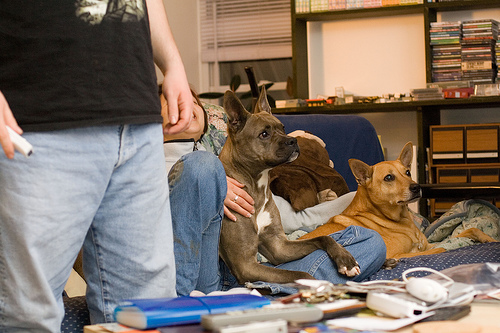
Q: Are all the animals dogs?
A: Yes, all the animals are dogs.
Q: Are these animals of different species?
A: No, all the animals are dogs.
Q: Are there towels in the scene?
A: No, there are no towels.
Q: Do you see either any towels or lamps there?
A: No, there are no towels or lamps.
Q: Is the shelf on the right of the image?
A: Yes, the shelf is on the right of the image.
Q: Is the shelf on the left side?
A: No, the shelf is on the right of the image.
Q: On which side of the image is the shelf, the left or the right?
A: The shelf is on the right of the image.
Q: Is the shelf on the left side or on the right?
A: The shelf is on the right of the image.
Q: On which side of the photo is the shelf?
A: The shelf is on the right of the image.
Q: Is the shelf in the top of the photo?
A: Yes, the shelf is in the top of the image.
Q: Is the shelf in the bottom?
A: No, the shelf is in the top of the image.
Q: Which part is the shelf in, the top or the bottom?
A: The shelf is in the top of the image.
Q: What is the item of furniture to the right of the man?
A: The piece of furniture is a shelf.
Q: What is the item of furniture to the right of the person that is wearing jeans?
A: The piece of furniture is a shelf.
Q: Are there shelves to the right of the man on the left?
A: Yes, there is a shelf to the right of the man.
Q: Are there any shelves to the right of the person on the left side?
A: Yes, there is a shelf to the right of the man.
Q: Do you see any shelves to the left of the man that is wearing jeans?
A: No, the shelf is to the right of the man.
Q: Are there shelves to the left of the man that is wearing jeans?
A: No, the shelf is to the right of the man.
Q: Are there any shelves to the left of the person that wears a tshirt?
A: No, the shelf is to the right of the man.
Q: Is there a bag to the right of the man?
A: No, there is a shelf to the right of the man.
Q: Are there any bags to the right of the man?
A: No, there is a shelf to the right of the man.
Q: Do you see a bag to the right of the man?
A: No, there is a shelf to the right of the man.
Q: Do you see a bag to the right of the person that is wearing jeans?
A: No, there is a shelf to the right of the man.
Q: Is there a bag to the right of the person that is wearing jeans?
A: No, there is a shelf to the right of the man.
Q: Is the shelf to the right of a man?
A: Yes, the shelf is to the right of a man.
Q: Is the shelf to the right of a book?
A: No, the shelf is to the right of a man.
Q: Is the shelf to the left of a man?
A: No, the shelf is to the right of a man.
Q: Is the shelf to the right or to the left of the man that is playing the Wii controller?
A: The shelf is to the right of the man.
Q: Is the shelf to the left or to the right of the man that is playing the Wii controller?
A: The shelf is to the right of the man.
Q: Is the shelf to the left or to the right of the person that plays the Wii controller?
A: The shelf is to the right of the man.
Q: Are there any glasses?
A: No, there are no glasses.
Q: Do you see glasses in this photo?
A: No, there are no glasses.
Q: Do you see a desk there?
A: Yes, there is a desk.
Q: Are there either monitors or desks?
A: Yes, there is a desk.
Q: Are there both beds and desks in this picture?
A: No, there is a desk but no beds.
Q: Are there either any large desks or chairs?
A: Yes, there is a large desk.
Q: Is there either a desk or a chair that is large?
A: Yes, the desk is large.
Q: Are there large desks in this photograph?
A: Yes, there is a large desk.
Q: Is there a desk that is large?
A: Yes, there is a desk that is large.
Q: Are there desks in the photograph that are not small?
A: Yes, there is a large desk.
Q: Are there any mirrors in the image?
A: No, there are no mirrors.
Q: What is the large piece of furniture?
A: The piece of furniture is a desk.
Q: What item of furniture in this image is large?
A: The piece of furniture is a desk.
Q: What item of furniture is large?
A: The piece of furniture is a desk.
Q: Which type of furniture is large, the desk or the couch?
A: The desk is large.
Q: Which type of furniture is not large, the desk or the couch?
A: The couch is not large.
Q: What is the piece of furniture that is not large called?
A: The piece of furniture is a couch.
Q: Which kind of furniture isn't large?
A: The furniture is a couch.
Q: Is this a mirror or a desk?
A: This is a desk.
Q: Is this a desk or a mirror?
A: This is a desk.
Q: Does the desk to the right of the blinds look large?
A: Yes, the desk is large.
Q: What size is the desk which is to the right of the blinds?
A: The desk is large.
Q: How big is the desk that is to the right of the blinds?
A: The desk is large.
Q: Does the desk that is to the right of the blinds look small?
A: No, the desk is large.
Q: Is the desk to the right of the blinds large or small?
A: The desk is large.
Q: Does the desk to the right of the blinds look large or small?
A: The desk is large.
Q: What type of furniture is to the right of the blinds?
A: The piece of furniture is a desk.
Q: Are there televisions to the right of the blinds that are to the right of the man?
A: No, there is a desk to the right of the blinds.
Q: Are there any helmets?
A: No, there are no helmets.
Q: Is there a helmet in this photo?
A: No, there are no helmets.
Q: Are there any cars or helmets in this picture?
A: No, there are no helmets or cars.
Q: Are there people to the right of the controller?
A: Yes, there is a person to the right of the controller.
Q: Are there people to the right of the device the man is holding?
A: Yes, there is a person to the right of the controller.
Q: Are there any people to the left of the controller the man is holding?
A: No, the person is to the right of the controller.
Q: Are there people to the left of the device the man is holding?
A: No, the person is to the right of the controller.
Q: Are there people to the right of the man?
A: Yes, there is a person to the right of the man.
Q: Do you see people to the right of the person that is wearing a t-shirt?
A: Yes, there is a person to the right of the man.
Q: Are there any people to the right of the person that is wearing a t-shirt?
A: Yes, there is a person to the right of the man.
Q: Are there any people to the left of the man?
A: No, the person is to the right of the man.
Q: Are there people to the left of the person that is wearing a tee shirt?
A: No, the person is to the right of the man.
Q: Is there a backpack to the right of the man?
A: No, there is a person to the right of the man.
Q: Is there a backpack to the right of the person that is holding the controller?
A: No, there is a person to the right of the man.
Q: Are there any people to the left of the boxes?
A: Yes, there is a person to the left of the boxes.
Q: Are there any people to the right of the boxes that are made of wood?
A: No, the person is to the left of the boxes.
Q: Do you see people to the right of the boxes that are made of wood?
A: No, the person is to the left of the boxes.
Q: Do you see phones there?
A: No, there are no phones.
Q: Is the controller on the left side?
A: Yes, the controller is on the left of the image.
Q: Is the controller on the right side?
A: No, the controller is on the left of the image.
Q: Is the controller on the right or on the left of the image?
A: The controller is on the left of the image.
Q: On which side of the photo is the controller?
A: The controller is on the left of the image.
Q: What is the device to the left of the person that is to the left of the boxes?
A: The device is a controller.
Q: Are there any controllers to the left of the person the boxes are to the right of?
A: Yes, there is a controller to the left of the person.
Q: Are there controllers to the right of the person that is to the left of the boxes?
A: No, the controller is to the left of the person.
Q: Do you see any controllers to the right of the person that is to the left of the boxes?
A: No, the controller is to the left of the person.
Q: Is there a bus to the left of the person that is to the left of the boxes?
A: No, there is a controller to the left of the person.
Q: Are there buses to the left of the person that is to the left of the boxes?
A: No, there is a controller to the left of the person.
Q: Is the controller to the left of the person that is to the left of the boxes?
A: Yes, the controller is to the left of the person.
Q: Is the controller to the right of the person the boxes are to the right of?
A: No, the controller is to the left of the person.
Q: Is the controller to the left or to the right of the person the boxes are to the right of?
A: The controller is to the left of the person.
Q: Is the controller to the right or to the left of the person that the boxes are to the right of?
A: The controller is to the left of the person.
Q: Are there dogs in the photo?
A: Yes, there is a dog.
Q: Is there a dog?
A: Yes, there is a dog.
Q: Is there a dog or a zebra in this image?
A: Yes, there is a dog.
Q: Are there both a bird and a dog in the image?
A: No, there is a dog but no birds.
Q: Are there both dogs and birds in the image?
A: No, there is a dog but no birds.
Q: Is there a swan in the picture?
A: No, there are no swans.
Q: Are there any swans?
A: No, there are no swans.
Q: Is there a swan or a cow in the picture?
A: No, there are no swans or cows.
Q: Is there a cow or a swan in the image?
A: No, there are no swans or cows.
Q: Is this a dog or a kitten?
A: This is a dog.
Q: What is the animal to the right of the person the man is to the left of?
A: The animal is a dog.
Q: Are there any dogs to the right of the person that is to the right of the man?
A: Yes, there is a dog to the right of the person.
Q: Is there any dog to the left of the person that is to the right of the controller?
A: No, the dog is to the right of the person.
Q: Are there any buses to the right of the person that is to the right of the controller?
A: No, there is a dog to the right of the person.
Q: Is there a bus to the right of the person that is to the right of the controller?
A: No, there is a dog to the right of the person.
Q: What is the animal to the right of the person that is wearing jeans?
A: The animal is a dog.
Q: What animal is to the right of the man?
A: The animal is a dog.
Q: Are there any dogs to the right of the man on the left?
A: Yes, there is a dog to the right of the man.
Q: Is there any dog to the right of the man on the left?
A: Yes, there is a dog to the right of the man.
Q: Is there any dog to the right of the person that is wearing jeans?
A: Yes, there is a dog to the right of the man.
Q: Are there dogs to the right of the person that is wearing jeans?
A: Yes, there is a dog to the right of the man.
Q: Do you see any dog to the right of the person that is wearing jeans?
A: Yes, there is a dog to the right of the man.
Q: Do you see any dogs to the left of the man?
A: No, the dog is to the right of the man.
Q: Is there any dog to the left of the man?
A: No, the dog is to the right of the man.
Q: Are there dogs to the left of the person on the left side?
A: No, the dog is to the right of the man.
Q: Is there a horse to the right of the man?
A: No, there is a dog to the right of the man.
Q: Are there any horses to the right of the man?
A: No, there is a dog to the right of the man.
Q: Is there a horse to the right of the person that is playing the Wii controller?
A: No, there is a dog to the right of the man.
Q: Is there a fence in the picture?
A: No, there are no fences.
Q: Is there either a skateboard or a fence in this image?
A: No, there are no fences or skateboards.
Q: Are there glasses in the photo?
A: No, there are no glasses.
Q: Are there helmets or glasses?
A: No, there are no glasses or helmets.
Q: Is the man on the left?
A: Yes, the man is on the left of the image.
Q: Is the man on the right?
A: No, the man is on the left of the image.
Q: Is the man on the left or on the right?
A: The man is on the left of the image.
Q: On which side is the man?
A: The man is on the left of the image.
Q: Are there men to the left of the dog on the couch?
A: Yes, there is a man to the left of the dog.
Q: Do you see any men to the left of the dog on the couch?
A: Yes, there is a man to the left of the dog.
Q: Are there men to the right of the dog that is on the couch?
A: No, the man is to the left of the dog.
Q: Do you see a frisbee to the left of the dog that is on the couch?
A: No, there is a man to the left of the dog.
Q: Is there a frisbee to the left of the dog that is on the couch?
A: No, there is a man to the left of the dog.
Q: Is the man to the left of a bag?
A: No, the man is to the left of a dog.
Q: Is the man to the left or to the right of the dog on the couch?
A: The man is to the left of the dog.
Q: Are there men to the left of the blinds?
A: Yes, there is a man to the left of the blinds.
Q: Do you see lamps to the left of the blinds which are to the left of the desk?
A: No, there is a man to the left of the blinds.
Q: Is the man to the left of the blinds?
A: Yes, the man is to the left of the blinds.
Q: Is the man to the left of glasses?
A: No, the man is to the left of the blinds.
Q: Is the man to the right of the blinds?
A: No, the man is to the left of the blinds.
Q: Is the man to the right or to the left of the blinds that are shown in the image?
A: The man is to the left of the blinds.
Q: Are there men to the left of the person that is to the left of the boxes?
A: Yes, there is a man to the left of the person.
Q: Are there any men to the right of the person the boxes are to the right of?
A: No, the man is to the left of the person.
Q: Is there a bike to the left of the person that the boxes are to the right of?
A: No, there is a man to the left of the person.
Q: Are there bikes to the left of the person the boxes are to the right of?
A: No, there is a man to the left of the person.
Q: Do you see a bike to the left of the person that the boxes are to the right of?
A: No, there is a man to the left of the person.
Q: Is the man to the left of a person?
A: Yes, the man is to the left of a person.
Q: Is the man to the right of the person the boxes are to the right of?
A: No, the man is to the left of the person.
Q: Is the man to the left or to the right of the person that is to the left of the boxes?
A: The man is to the left of the person.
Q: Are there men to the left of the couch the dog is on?
A: Yes, there is a man to the left of the couch.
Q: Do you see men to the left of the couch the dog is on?
A: Yes, there is a man to the left of the couch.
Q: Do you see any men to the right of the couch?
A: No, the man is to the left of the couch.